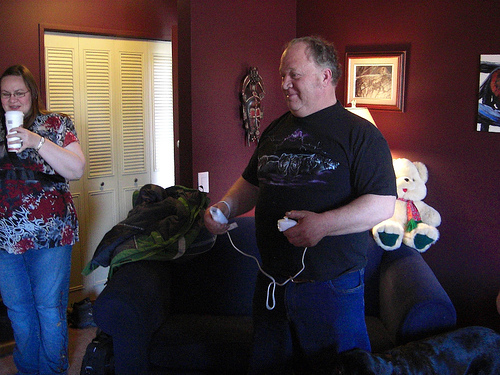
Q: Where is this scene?
A: Living room.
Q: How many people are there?
A: Two.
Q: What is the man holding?
A: Wii controller.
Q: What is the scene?
A: Indoor.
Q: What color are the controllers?
A: White.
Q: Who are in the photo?
A: People.